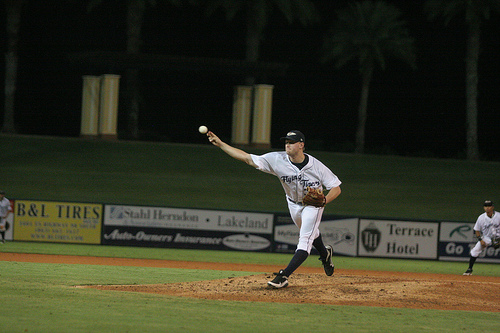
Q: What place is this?
A: It is a field.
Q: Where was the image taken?
A: It was taken at the field.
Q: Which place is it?
A: It is a field.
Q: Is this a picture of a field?
A: Yes, it is showing a field.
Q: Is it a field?
A: Yes, it is a field.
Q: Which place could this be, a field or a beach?
A: It is a field.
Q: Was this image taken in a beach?
A: No, the picture was taken in a field.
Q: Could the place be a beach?
A: No, it is a field.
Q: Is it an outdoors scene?
A: Yes, it is outdoors.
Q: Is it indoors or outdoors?
A: It is outdoors.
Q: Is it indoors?
A: No, it is outdoors.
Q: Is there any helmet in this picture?
A: No, there are no helmets.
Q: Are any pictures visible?
A: No, there are no pictures.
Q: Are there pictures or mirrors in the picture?
A: No, there are no pictures or mirrors.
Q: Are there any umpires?
A: No, there are no umpires.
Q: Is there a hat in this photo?
A: Yes, there is a hat.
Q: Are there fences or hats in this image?
A: Yes, there is a hat.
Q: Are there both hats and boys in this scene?
A: No, there is a hat but no boys.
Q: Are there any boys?
A: No, there are no boys.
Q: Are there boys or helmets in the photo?
A: No, there are no boys or helmets.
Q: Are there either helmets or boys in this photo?
A: No, there are no boys or helmets.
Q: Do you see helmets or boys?
A: No, there are no boys or helmets.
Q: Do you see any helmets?
A: No, there are no helmets.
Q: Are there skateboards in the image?
A: No, there are no skateboards.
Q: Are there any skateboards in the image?
A: No, there are no skateboards.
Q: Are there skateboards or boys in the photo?
A: No, there are no skateboards or boys.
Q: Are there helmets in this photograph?
A: No, there are no helmets.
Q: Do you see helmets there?
A: No, there are no helmets.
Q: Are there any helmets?
A: No, there are no helmets.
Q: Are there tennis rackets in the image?
A: No, there are no tennis rackets.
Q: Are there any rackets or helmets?
A: No, there are no rackets or helmets.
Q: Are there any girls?
A: No, there are no girls.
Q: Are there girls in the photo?
A: No, there are no girls.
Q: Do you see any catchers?
A: No, there are no catchers.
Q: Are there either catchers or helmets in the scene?
A: No, there are no catchers or helmets.